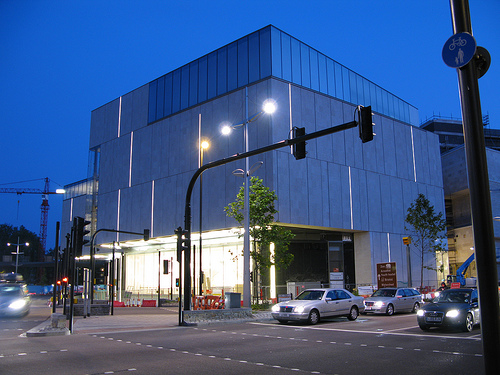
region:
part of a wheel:
[317, 304, 329, 318]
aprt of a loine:
[177, 331, 203, 371]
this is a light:
[249, 95, 294, 117]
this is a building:
[82, 26, 440, 309]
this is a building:
[51, 182, 96, 297]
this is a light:
[210, 118, 240, 147]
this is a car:
[262, 288, 371, 325]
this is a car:
[363, 287, 418, 320]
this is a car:
[419, 287, 476, 339]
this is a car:
[2, 278, 35, 333]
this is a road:
[4, 325, 481, 369]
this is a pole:
[446, 0, 498, 374]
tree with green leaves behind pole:
[228, 176, 300, 280]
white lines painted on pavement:
[150, 345, 253, 370]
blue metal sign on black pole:
[431, 28, 481, 72]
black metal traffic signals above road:
[277, 100, 387, 165]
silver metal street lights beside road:
[205, 94, 285, 141]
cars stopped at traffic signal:
[261, 274, 482, 339]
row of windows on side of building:
[134, 19, 381, 104]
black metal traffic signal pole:
[183, 125, 289, 177]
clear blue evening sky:
[9, 25, 134, 92]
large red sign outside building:
[373, 257, 402, 289]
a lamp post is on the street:
[220, 90, 282, 305]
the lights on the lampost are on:
[215, 97, 279, 140]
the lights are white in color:
[218, 94, 278, 142]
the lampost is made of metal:
[218, 87, 275, 307]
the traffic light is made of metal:
[183, 110, 377, 320]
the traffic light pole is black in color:
[173, 102, 382, 320]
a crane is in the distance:
[6, 173, 61, 243]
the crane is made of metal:
[9, 172, 71, 249]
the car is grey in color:
[272, 281, 364, 326]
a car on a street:
[277, 275, 364, 332]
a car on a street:
[361, 275, 421, 318]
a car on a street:
[6, 280, 31, 317]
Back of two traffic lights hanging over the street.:
[285, 100, 390, 162]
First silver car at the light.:
[268, 285, 365, 325]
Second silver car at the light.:
[364, 285, 424, 314]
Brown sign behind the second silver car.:
[376, 262, 398, 287]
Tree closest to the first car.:
[225, 175, 297, 308]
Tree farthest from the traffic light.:
[404, 191, 447, 296]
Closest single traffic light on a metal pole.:
[67, 214, 92, 334]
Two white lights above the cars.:
[215, 99, 277, 135]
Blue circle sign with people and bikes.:
[438, 30, 480, 73]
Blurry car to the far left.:
[0, 280, 34, 315]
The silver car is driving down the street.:
[265, 282, 364, 322]